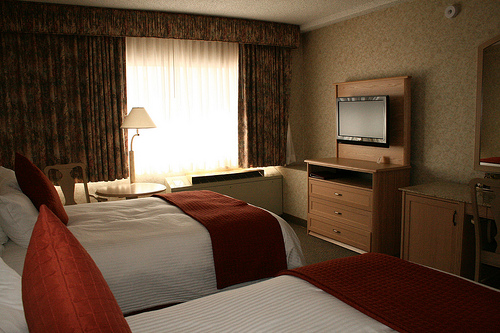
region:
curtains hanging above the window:
[27, 60, 89, 120]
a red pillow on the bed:
[33, 226, 104, 331]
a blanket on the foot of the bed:
[334, 245, 401, 320]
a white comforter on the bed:
[95, 205, 155, 258]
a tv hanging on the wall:
[341, 82, 388, 149]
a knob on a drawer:
[331, 178, 344, 208]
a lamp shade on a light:
[116, 95, 156, 138]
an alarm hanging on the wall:
[434, 10, 468, 20]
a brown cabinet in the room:
[318, 154, 392, 250]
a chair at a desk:
[467, 171, 499, 263]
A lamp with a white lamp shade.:
[112, 106, 154, 183]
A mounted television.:
[332, 93, 394, 150]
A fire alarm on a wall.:
[442, 3, 455, 20]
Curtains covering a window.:
[5, 36, 292, 172]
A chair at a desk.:
[462, 171, 496, 285]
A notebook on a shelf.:
[307, 168, 334, 180]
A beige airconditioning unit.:
[167, 158, 293, 215]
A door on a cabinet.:
[400, 186, 466, 273]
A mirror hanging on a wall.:
[471, 35, 498, 175]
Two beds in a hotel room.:
[2, 158, 498, 329]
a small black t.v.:
[335, 96, 389, 146]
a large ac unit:
[162, 168, 284, 215]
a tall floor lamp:
[115, 104, 153, 186]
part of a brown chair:
[45, 160, 89, 202]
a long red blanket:
[155, 182, 293, 291]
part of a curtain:
[231, 46, 298, 170]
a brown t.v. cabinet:
[305, 148, 390, 253]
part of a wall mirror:
[473, 38, 498, 168]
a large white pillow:
[2, 188, 39, 242]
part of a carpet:
[278, 207, 341, 263]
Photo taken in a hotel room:
[9, 14, 494, 322]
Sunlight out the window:
[112, 24, 258, 189]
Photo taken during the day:
[3, 26, 485, 329]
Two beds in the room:
[3, 205, 483, 320]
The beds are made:
[2, 163, 492, 326]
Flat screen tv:
[316, 75, 403, 154]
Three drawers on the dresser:
[294, 174, 382, 252]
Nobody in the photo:
[10, 9, 494, 328]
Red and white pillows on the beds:
[7, 169, 127, 325]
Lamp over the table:
[120, 104, 160, 187]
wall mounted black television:
[330, 90, 396, 148]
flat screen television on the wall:
[334, 90, 392, 147]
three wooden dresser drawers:
[310, 175, 374, 250]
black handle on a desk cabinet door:
[453, 203, 460, 226]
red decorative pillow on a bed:
[14, 211, 108, 331]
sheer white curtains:
[140, 50, 232, 132]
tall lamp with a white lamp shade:
[114, 99, 163, 198]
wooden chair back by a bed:
[44, 153, 99, 209]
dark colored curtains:
[12, 32, 114, 135]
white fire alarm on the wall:
[437, 4, 464, 23]